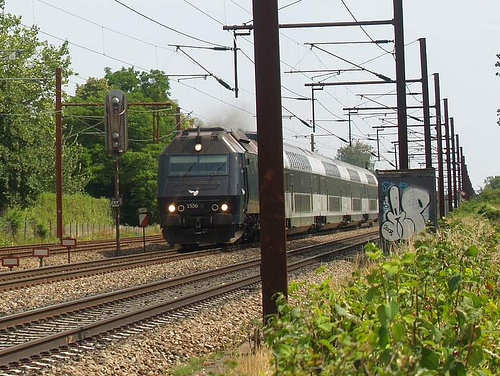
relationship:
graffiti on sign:
[381, 168, 439, 260] [391, 188, 432, 242]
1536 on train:
[184, 201, 200, 211] [157, 130, 380, 250]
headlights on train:
[166, 143, 227, 212] [157, 130, 380, 250]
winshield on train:
[169, 154, 226, 175] [157, 130, 380, 250]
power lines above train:
[0, 3, 460, 195] [157, 130, 380, 250]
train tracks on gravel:
[0, 219, 381, 369] [2, 219, 389, 375]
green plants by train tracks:
[252, 176, 499, 374] [0, 219, 381, 369]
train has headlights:
[157, 130, 380, 250] [166, 143, 227, 212]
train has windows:
[157, 130, 380, 250] [284, 149, 311, 171]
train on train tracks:
[157, 130, 380, 250] [0, 219, 381, 369]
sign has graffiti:
[391, 188, 432, 242] [381, 168, 439, 260]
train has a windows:
[157, 130, 380, 250] [169, 154, 226, 175]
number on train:
[185, 201, 198, 210] [157, 130, 380, 250]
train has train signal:
[157, 130, 380, 250] [105, 89, 129, 158]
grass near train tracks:
[169, 329, 270, 374] [0, 219, 381, 369]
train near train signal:
[157, 130, 380, 250] [105, 89, 129, 158]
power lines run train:
[0, 3, 460, 195] [157, 130, 380, 250]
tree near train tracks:
[69, 63, 179, 194] [0, 219, 381, 369]